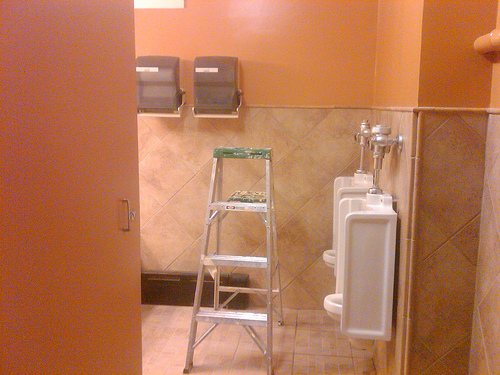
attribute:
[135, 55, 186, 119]
towel dispenser — to the left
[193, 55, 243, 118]
towel dispenser — to the right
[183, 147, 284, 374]
ladder — set up, metal, aluminum, short, tall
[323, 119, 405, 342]
urinals — porcelain, white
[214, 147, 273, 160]
top — green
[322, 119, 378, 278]
urinal — to the left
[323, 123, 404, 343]
urinal — to the right, in foreground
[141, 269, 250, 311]
object — black, rectangular, dark brown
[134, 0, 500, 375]
wall — Ceramic , smooth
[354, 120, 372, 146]
flusher — metal, silver, chrome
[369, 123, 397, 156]
flusher — metal, chrome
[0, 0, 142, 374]
door — open, orange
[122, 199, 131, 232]
handle — silver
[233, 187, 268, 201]
paint — dried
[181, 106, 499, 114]
border — tile, rounded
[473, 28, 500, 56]
pipe — painted, orange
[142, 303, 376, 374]
floor — tile